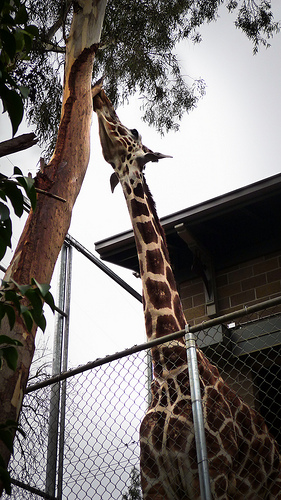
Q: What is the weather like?
A: It is cloudy.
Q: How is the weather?
A: It is cloudy.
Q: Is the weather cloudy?
A: Yes, it is cloudy.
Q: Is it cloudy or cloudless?
A: It is cloudy.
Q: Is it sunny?
A: No, it is cloudy.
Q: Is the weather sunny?
A: No, it is cloudy.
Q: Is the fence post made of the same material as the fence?
A: Yes, both the post and the fence are made of metal.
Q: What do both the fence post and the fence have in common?
A: The material, both the post and the fence are metallic.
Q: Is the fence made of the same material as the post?
A: Yes, both the fence and the post are made of metal.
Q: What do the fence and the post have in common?
A: The material, both the fence and the post are metallic.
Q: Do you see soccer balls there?
A: No, there are no soccer balls.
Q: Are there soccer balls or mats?
A: No, there are no soccer balls or mats.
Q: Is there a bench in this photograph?
A: No, there are no benches.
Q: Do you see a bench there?
A: No, there are no benches.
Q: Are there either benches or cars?
A: No, there are no benches or cars.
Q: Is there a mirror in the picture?
A: No, there are no mirrors.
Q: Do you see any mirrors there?
A: No, there are no mirrors.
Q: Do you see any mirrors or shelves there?
A: No, there are no mirrors or shelves.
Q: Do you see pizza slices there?
A: No, there are no pizza slices.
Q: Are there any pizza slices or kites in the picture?
A: No, there are no pizza slices or kites.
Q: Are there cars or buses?
A: No, there are no cars or buses.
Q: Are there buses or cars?
A: No, there are no cars or buses.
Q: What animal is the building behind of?
A: The building is behind the giraffe.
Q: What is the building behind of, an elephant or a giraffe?
A: The building is behind a giraffe.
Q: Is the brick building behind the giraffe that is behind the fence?
A: Yes, the building is behind the giraffe.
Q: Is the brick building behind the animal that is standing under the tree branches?
A: Yes, the building is behind the giraffe.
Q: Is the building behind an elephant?
A: No, the building is behind the giraffe.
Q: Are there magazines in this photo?
A: No, there are no magazines.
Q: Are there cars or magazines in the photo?
A: No, there are no magazines or cars.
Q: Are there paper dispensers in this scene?
A: No, there are no paper dispensers.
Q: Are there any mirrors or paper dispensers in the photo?
A: No, there are no paper dispensers or mirrors.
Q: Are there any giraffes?
A: Yes, there is a giraffe.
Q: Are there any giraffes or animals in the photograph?
A: Yes, there is a giraffe.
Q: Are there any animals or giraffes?
A: Yes, there is a giraffe.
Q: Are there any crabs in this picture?
A: No, there are no crabs.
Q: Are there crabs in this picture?
A: No, there are no crabs.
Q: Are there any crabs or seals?
A: No, there are no crabs or seals.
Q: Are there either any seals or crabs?
A: No, there are no crabs or seals.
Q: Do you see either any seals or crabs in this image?
A: No, there are no crabs or seals.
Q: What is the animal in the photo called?
A: The animal is a giraffe.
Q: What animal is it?
A: The animal is a giraffe.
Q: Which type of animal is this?
A: This is a giraffe.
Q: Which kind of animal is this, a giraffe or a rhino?
A: This is a giraffe.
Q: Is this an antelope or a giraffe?
A: This is a giraffe.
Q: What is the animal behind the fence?
A: The animal is a giraffe.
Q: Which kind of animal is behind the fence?
A: The animal is a giraffe.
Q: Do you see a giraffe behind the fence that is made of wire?
A: Yes, there is a giraffe behind the fence.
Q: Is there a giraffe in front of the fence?
A: No, the giraffe is behind the fence.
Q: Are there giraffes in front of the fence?
A: No, the giraffe is behind the fence.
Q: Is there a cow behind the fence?
A: No, there is a giraffe behind the fence.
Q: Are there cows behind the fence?
A: No, there is a giraffe behind the fence.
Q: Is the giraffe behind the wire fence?
A: Yes, the giraffe is behind the fence.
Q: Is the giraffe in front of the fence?
A: No, the giraffe is behind the fence.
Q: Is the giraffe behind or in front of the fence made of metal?
A: The giraffe is behind the fence.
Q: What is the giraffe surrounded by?
A: The giraffe is surrounded by the fence.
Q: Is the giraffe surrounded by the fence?
A: Yes, the giraffe is surrounded by the fence.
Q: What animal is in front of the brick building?
A: The giraffe is in front of the building.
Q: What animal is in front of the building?
A: The giraffe is in front of the building.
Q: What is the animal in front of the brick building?
A: The animal is a giraffe.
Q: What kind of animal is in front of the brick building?
A: The animal is a giraffe.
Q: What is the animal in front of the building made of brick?
A: The animal is a giraffe.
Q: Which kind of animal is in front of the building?
A: The animal is a giraffe.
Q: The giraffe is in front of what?
A: The giraffe is in front of the building.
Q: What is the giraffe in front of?
A: The giraffe is in front of the building.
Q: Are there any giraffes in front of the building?
A: Yes, there is a giraffe in front of the building.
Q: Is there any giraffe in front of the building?
A: Yes, there is a giraffe in front of the building.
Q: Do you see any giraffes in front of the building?
A: Yes, there is a giraffe in front of the building.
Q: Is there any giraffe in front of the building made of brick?
A: Yes, there is a giraffe in front of the building.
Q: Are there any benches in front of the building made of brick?
A: No, there is a giraffe in front of the building.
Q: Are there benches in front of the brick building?
A: No, there is a giraffe in front of the building.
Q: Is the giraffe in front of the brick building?
A: Yes, the giraffe is in front of the building.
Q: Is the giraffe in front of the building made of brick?
A: Yes, the giraffe is in front of the building.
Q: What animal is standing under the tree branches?
A: The giraffe is standing under the tree branches.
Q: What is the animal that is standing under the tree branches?
A: The animal is a giraffe.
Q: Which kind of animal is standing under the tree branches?
A: The animal is a giraffe.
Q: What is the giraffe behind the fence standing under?
A: The giraffe is standing under the tree branches.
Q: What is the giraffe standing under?
A: The giraffe is standing under the tree branches.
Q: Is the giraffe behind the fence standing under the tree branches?
A: Yes, the giraffe is standing under the tree branches.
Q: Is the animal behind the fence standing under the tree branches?
A: Yes, the giraffe is standing under the tree branches.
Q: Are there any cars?
A: No, there are no cars.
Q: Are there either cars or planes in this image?
A: No, there are no cars or planes.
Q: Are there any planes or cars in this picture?
A: No, there are no cars or planes.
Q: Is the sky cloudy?
A: Yes, the sky is cloudy.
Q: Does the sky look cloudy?
A: Yes, the sky is cloudy.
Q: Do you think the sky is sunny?
A: No, the sky is cloudy.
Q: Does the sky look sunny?
A: No, the sky is cloudy.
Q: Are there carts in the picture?
A: No, there are no carts.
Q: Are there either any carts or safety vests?
A: No, there are no carts or safety vests.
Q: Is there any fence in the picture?
A: Yes, there is a fence.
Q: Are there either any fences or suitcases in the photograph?
A: Yes, there is a fence.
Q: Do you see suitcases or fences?
A: Yes, there is a fence.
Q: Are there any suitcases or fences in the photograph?
A: Yes, there is a fence.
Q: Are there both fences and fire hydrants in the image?
A: No, there is a fence but no fire hydrants.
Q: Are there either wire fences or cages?
A: Yes, there is a wire fence.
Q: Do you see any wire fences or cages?
A: Yes, there is a wire fence.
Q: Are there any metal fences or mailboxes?
A: Yes, there is a metal fence.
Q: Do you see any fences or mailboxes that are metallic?
A: Yes, the fence is metallic.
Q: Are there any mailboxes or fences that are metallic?
A: Yes, the fence is metallic.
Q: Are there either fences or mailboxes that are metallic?
A: Yes, the fence is metallic.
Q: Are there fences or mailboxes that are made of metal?
A: Yes, the fence is made of metal.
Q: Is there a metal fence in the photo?
A: Yes, there is a metal fence.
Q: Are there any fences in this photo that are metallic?
A: Yes, there is a fence that is metallic.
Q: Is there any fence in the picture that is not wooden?
A: Yes, there is a metallic fence.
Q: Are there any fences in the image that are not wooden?
A: Yes, there is a metallic fence.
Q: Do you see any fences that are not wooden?
A: Yes, there is a metallic fence.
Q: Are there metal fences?
A: Yes, there is a fence that is made of metal.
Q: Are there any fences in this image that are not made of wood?
A: Yes, there is a fence that is made of metal.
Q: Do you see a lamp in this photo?
A: No, there are no lamps.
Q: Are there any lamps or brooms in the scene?
A: No, there are no lamps or brooms.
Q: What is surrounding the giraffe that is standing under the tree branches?
A: The fence is surrounding the giraffe.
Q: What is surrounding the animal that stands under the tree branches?
A: The fence is surrounding the giraffe.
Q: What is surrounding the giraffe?
A: The fence is surrounding the giraffe.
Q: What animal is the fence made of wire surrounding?
A: The fence is surrounding the giraffe.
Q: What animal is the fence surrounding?
A: The fence is surrounding the giraffe.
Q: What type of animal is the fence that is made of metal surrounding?
A: The fence is surrounding the giraffe.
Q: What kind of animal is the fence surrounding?
A: The fence is surrounding the giraffe.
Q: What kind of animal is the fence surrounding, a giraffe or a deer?
A: The fence is surrounding a giraffe.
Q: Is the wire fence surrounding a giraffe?
A: Yes, the fence is surrounding a giraffe.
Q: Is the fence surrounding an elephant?
A: No, the fence is surrounding a giraffe.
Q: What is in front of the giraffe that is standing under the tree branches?
A: The fence is in front of the giraffe.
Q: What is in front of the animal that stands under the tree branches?
A: The fence is in front of the giraffe.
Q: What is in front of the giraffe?
A: The fence is in front of the giraffe.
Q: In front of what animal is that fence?
A: The fence is in front of the giraffe.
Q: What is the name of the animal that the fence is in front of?
A: The animal is a giraffe.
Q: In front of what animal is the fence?
A: The fence is in front of the giraffe.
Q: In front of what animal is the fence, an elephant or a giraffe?
A: The fence is in front of a giraffe.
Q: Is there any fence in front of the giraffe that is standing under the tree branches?
A: Yes, there is a fence in front of the giraffe.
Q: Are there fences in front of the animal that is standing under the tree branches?
A: Yes, there is a fence in front of the giraffe.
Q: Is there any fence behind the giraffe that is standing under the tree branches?
A: No, the fence is in front of the giraffe.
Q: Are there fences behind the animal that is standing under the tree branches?
A: No, the fence is in front of the giraffe.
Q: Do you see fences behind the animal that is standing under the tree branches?
A: No, the fence is in front of the giraffe.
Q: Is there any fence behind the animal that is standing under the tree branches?
A: No, the fence is in front of the giraffe.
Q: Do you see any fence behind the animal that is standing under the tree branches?
A: No, the fence is in front of the giraffe.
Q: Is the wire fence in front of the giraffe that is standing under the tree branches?
A: Yes, the fence is in front of the giraffe.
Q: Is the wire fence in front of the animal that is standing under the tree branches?
A: Yes, the fence is in front of the giraffe.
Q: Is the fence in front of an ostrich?
A: No, the fence is in front of the giraffe.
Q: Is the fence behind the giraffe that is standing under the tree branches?
A: No, the fence is in front of the giraffe.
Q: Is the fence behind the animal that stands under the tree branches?
A: No, the fence is in front of the giraffe.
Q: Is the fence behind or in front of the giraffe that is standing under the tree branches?
A: The fence is in front of the giraffe.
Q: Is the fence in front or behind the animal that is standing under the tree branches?
A: The fence is in front of the giraffe.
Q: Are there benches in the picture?
A: No, there are no benches.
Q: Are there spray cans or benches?
A: No, there are no benches or spray cans.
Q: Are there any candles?
A: No, there are no candles.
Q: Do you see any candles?
A: No, there are no candles.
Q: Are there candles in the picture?
A: No, there are no candles.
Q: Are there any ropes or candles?
A: No, there are no candles or ropes.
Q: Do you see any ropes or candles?
A: No, there are no candles or ropes.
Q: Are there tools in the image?
A: No, there are no tools.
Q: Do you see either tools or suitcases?
A: No, there are no tools or suitcases.